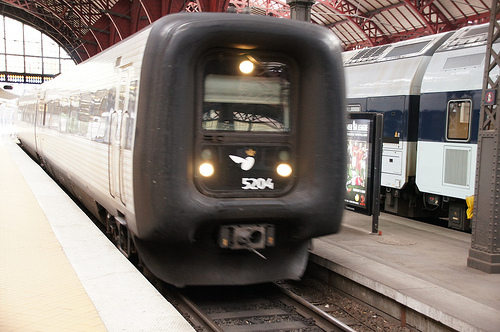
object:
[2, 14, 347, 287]
train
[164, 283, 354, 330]
tracks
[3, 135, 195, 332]
platform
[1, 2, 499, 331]
station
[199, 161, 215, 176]
light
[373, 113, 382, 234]
post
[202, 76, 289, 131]
window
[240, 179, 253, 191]
number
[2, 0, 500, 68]
roof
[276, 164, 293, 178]
light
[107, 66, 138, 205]
door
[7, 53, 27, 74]
window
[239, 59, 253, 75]
light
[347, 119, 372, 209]
poster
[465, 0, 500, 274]
support beam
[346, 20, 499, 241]
train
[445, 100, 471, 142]
window